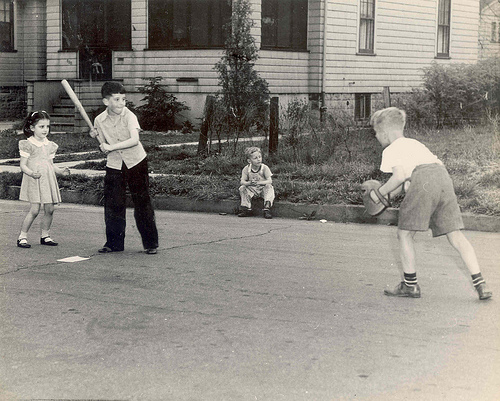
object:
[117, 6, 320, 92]
white siding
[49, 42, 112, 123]
porch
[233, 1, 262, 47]
siding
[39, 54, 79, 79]
siding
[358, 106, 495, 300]
boy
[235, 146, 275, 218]
boy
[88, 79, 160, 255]
boy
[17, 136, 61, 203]
dress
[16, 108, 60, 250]
girl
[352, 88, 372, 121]
porch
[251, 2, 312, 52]
porch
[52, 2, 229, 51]
porch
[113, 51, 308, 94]
siding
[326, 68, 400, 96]
siding